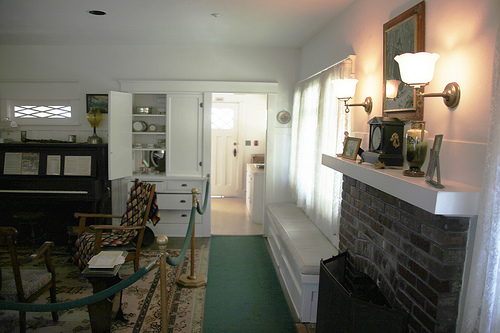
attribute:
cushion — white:
[251, 161, 354, 293]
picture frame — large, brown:
[380, 2, 425, 121]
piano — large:
[0, 142, 109, 247]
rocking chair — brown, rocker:
[75, 180, 157, 266]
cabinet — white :
[115, 85, 202, 237]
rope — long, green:
[162, 201, 194, 282]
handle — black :
[180, 180, 190, 187]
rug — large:
[3, 239, 209, 331]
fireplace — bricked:
[322, 189, 460, 321]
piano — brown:
[3, 137, 110, 244]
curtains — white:
[292, 63, 354, 235]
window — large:
[293, 65, 352, 235]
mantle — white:
[319, 152, 481, 215]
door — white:
[208, 97, 244, 202]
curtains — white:
[289, 60, 349, 226]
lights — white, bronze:
[324, 50, 459, 115]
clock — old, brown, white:
[367, 113, 406, 166]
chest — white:
[258, 212, 316, 317]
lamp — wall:
[392, 53, 467, 119]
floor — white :
[207, 198, 249, 258]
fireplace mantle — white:
[321, 154, 484, 214]